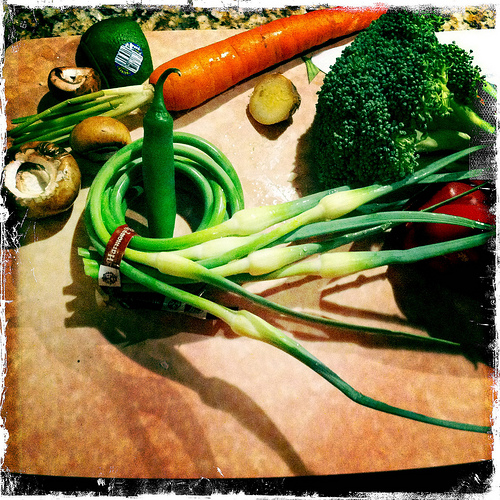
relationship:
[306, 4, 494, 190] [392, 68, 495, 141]
broccoli has floret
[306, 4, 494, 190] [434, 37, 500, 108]
broccoli has floret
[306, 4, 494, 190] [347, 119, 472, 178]
broccoli has floret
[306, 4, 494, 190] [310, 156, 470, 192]
broccoli has floret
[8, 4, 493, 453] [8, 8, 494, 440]
ingredients for salad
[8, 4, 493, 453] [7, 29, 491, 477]
ingredients on cutting board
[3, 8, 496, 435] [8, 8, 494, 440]
vegetables for salad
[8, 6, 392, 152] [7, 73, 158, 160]
carrot has top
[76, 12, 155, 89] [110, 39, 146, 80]
lime has sticker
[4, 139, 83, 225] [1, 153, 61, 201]
mushroom has underside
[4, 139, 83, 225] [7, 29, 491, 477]
mushroom on cutting board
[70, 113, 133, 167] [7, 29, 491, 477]
mushroom on cutting board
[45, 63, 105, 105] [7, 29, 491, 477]
mushroom on cutting board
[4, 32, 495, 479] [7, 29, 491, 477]
shadow on cutting board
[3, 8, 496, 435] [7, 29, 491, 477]
vegetables on cutting board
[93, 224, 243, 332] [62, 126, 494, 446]
twist tie on hard neck garlic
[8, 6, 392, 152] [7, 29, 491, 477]
carrot on cutting board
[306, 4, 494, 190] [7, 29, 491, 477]
broccoli on cutting board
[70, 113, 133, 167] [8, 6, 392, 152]
mushroom beside carrot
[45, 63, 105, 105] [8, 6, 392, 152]
mushroom beside carrot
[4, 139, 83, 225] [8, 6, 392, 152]
mushroom beside carrot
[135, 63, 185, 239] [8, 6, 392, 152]
pepper beside carrot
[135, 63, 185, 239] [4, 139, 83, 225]
pepper beside mushroom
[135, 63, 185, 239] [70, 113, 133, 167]
pepper beside mushroom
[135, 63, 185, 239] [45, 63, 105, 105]
pepper beside mushroom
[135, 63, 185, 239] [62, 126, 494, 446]
pepper inside circle of hard neck garlic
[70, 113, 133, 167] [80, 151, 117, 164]
mushroom on its side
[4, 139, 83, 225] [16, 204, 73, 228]
mushroom on its back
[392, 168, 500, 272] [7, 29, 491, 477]
pepper on cutting board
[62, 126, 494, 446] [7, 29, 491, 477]
hard neck garlic on cutting board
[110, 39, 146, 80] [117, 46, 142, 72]
sticker has barcode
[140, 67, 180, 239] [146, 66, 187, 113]
pepper has stem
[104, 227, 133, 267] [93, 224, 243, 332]
'harmony' on twist tie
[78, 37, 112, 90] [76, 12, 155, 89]
seam on lime